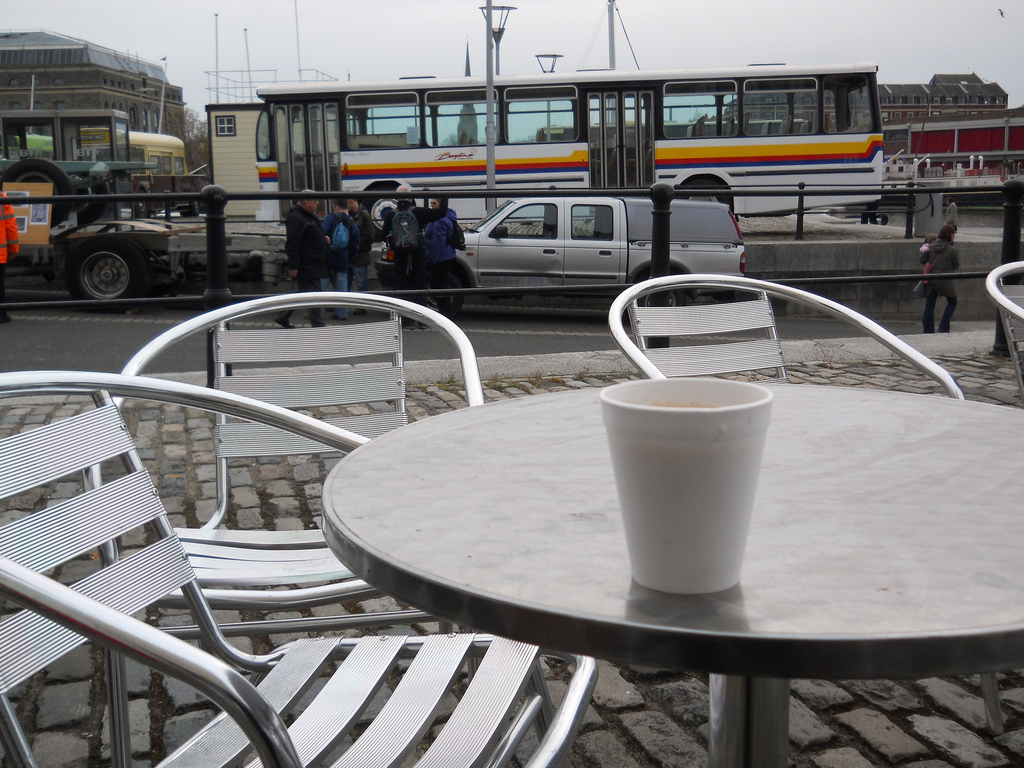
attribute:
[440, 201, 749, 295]
truck — silver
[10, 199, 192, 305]
truck — large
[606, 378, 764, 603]
cup — white, styrofoam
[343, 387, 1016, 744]
table — metal, circular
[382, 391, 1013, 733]
table — circular, metal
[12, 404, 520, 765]
chair — metal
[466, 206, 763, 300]
truck — gray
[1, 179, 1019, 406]
fence — black, iron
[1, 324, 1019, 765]
terrace — brown, brick, uneven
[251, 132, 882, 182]
stripe —  colorful 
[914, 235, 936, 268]
baby —  woman's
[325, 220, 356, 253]
backpack —  blue,  person's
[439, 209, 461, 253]
purse —  black,  woman's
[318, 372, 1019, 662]
table —  shiny,  metal,  circular,  silver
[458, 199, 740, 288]
truck —  old,  silver,  pickup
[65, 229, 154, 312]
wheel —  large,   black,  with silver rim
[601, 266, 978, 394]
chair —  silver,  metal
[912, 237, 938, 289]
child —    small ,  person's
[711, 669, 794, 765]
post —  table's,  silver,  metal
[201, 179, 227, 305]
post —  black,  metal,  railing's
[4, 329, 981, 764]
sidewalk — brick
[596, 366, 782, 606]
cup — white, Styrofoam,  white,  Styrofoam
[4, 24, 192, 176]
building — brown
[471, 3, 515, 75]
street lamp — black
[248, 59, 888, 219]
bus — white,  white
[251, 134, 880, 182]
lines — colorful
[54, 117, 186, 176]
bus — yellow, small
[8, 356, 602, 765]
chair — silver, shiny, metal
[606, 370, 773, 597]
cup — white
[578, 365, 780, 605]
cup — styrofoam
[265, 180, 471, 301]
people — some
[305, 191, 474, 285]
people — some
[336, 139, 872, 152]
stripe — yellow, red, blue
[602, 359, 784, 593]
cup — white, paper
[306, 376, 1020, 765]
table — outdoor, metal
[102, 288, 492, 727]
chair — silver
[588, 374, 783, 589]
cup — white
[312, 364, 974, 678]
table — silver, round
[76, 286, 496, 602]
chair — silver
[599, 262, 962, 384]
chair — silver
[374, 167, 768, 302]
car — silver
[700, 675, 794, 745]
leg — silver, central